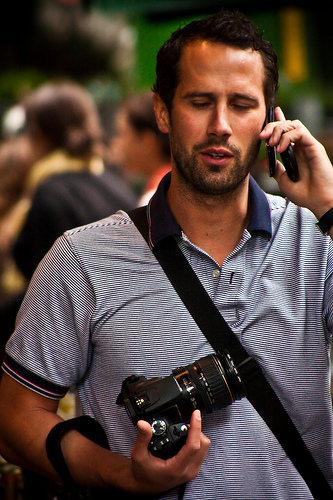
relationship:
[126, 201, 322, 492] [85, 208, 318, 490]
strap across chest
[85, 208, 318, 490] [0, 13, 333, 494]
chest of cameraman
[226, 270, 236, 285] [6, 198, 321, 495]
hole in shirt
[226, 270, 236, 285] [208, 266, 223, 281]
hole for button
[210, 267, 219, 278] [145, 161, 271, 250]
button near collar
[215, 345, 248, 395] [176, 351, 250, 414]
tip of lens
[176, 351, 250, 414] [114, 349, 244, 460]
lens of camera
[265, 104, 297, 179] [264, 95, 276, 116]
cellphone next to ear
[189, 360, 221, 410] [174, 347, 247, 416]
dial on lens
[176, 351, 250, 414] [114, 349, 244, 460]
lens on camera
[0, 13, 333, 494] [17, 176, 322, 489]
cameraman wearing shirt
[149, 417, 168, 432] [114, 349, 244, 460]
button on camera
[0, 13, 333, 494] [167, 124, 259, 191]
cameraman has beard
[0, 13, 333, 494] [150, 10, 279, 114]
cameraman has hair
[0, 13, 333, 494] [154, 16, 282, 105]
cameraman has hair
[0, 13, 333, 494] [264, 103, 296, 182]
cameraman holding cell phone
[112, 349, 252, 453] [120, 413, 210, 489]
camera in hand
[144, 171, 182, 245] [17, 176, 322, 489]
collar on shirt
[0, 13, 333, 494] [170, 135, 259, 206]
cameraman has beard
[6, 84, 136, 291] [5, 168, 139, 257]
person wearing shirt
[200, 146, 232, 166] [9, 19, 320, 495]
mouth of cameraman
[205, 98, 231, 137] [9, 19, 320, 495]
nose of cameraman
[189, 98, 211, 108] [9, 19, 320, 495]
eye of cameraman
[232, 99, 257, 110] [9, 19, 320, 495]
eye of cameraman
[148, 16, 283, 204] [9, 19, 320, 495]
head of cameraman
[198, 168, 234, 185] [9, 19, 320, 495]
chin of cameraman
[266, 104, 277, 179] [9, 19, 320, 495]
cellphone of cameraman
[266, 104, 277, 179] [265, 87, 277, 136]
cellphone to ear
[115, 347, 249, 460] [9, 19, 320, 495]
camera held by cameraman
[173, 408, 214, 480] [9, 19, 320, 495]
fingers of cameraman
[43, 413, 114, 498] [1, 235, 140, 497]
camera strap wrapped around arm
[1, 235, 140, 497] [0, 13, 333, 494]
arm belonging to cameraman